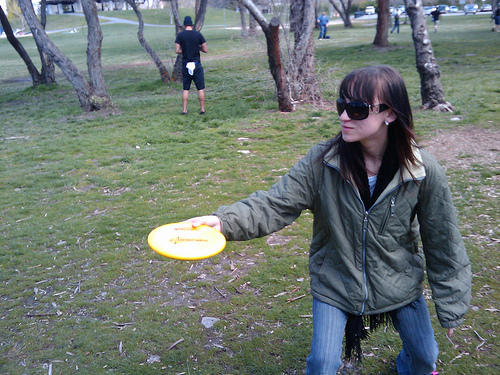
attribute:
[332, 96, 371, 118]
sunglasses — large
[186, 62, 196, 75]
towel — white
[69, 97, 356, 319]
grass — patchy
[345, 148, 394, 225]
scarf — black, hanging down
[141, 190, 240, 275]
frisbee — yellow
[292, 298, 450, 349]
jeans — blue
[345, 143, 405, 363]
scarf — black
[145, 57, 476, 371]
woman — young, ready to throw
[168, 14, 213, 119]
man — young, turned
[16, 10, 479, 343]
park — public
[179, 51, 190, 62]
beanie — black